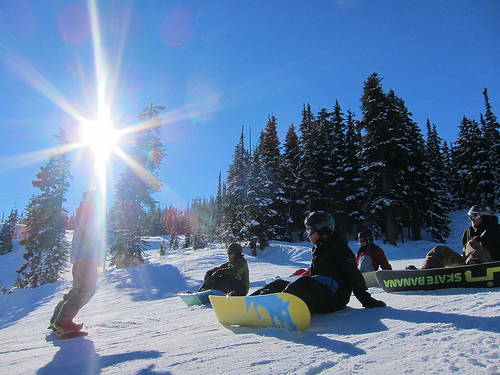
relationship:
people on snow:
[184, 218, 491, 305] [8, 215, 490, 367]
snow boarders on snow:
[184, 218, 491, 305] [8, 215, 490, 367]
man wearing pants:
[59, 231, 111, 334] [57, 258, 93, 327]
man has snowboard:
[59, 231, 111, 334] [51, 314, 84, 344]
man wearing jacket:
[59, 231, 111, 334] [72, 206, 106, 281]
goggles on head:
[304, 225, 337, 235] [304, 212, 336, 244]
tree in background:
[366, 80, 445, 236] [19, 133, 482, 270]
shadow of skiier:
[46, 322, 187, 374] [59, 231, 111, 334]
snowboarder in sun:
[59, 231, 111, 334] [69, 56, 135, 195]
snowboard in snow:
[51, 314, 84, 344] [8, 215, 490, 367]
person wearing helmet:
[59, 231, 111, 334] [83, 182, 102, 207]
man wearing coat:
[59, 231, 111, 334] [68, 209, 115, 265]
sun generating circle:
[69, 56, 135, 195] [54, 75, 161, 158]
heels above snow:
[51, 314, 84, 344] [8, 215, 490, 367]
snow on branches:
[8, 215, 490, 367] [239, 128, 423, 214]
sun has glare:
[69, 56, 135, 195] [51, 64, 177, 183]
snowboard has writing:
[51, 314, 84, 344] [382, 267, 497, 286]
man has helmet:
[59, 231, 111, 334] [83, 182, 102, 207]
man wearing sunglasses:
[59, 231, 111, 334] [304, 225, 337, 235]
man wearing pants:
[244, 208, 386, 320] [249, 275, 347, 315]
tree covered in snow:
[357, 70, 421, 249] [2, 133, 495, 373]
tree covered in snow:
[423, 120, 453, 243] [2, 133, 495, 373]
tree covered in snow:
[325, 98, 358, 239] [2, 133, 495, 373]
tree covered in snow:
[239, 110, 289, 240] [2, 133, 495, 373]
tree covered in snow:
[300, 101, 333, 241] [2, 133, 495, 373]